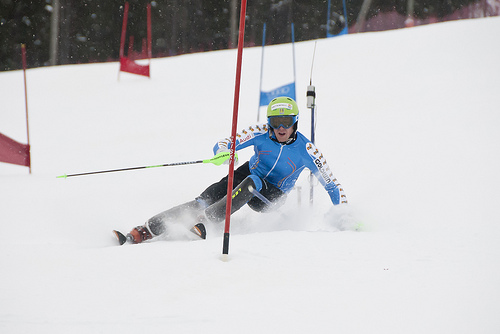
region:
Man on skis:
[90, 205, 219, 251]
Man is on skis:
[100, 216, 214, 251]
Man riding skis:
[92, 220, 218, 247]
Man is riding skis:
[96, 219, 226, 249]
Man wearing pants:
[141, 170, 293, 232]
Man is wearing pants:
[133, 172, 286, 234]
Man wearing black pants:
[135, 175, 292, 235]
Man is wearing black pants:
[135, 175, 285, 236]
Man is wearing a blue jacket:
[214, 125, 352, 215]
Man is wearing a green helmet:
[265, 91, 297, 128]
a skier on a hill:
[102, 85, 357, 260]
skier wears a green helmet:
[236, 86, 329, 173]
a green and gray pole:
[48, 149, 240, 187]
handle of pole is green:
[202, 142, 244, 169]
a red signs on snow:
[113, 0, 159, 85]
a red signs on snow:
[4, 37, 36, 177]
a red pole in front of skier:
[216, 0, 252, 257]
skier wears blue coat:
[97, 92, 361, 257]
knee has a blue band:
[239, 169, 269, 199]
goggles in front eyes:
[262, 114, 302, 145]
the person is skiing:
[81, 58, 341, 262]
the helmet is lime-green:
[247, 88, 312, 143]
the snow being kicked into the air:
[160, 203, 192, 250]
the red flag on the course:
[1, 41, 41, 171]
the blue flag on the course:
[256, 16, 297, 98]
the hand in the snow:
[333, 210, 368, 234]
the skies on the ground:
[113, 215, 210, 247]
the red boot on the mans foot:
[126, 216, 156, 247]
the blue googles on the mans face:
[266, 110, 298, 127]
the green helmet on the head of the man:
[267, 96, 298, 116]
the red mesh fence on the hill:
[343, 0, 494, 38]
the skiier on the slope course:
[51, 96, 360, 270]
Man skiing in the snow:
[121, 54, 390, 297]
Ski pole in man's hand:
[63, 100, 246, 190]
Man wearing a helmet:
[252, 79, 335, 167]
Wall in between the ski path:
[92, 5, 173, 80]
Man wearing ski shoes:
[95, 216, 172, 247]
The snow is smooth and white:
[355, 60, 495, 210]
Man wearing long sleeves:
[207, 108, 365, 250]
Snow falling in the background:
[188, 12, 231, 47]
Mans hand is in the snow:
[324, 193, 365, 245]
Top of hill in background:
[385, 13, 439, 52]